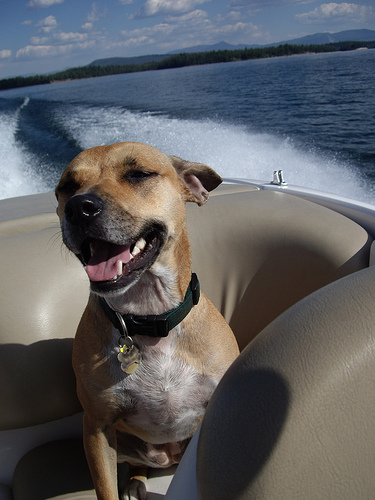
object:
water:
[1, 42, 375, 216]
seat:
[1, 172, 374, 497]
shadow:
[1, 333, 93, 497]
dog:
[54, 140, 239, 498]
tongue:
[87, 243, 131, 281]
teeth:
[132, 235, 146, 256]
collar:
[99, 272, 200, 341]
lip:
[73, 229, 164, 287]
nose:
[65, 194, 104, 221]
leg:
[84, 414, 119, 499]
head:
[53, 141, 222, 303]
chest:
[102, 342, 214, 447]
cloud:
[17, 15, 61, 37]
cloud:
[79, 17, 97, 32]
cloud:
[160, 7, 211, 28]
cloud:
[284, 1, 374, 34]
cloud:
[108, 33, 158, 53]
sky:
[1, 0, 374, 79]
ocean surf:
[1, 97, 374, 233]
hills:
[293, 30, 373, 45]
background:
[1, 21, 374, 98]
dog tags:
[115, 311, 142, 375]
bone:
[118, 345, 142, 371]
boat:
[0, 182, 375, 499]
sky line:
[1, 24, 374, 90]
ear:
[164, 155, 223, 207]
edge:
[186, 265, 353, 499]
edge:
[79, 428, 100, 499]